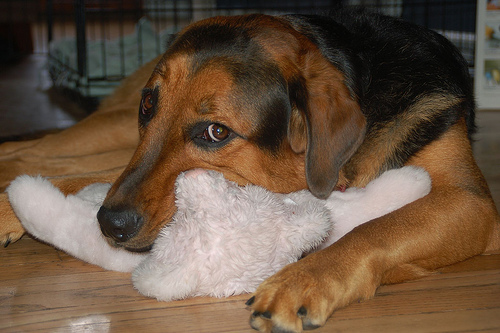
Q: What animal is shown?
A: Dog.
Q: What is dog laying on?
A: Toy.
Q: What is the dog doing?
A: Lying down.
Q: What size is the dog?
A: Large.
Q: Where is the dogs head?
A: On the toy.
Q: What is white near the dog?
A: Stuffed animal.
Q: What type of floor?
A: Wood.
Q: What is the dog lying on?
A: Wood floor.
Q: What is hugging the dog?
A: Stuffed animal.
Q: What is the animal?
A: Dog.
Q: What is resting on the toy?
A: Dog's head.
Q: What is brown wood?
A: Floor.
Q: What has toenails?
A: Dog paws.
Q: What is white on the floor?
A: Dog toy.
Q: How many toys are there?
A: One.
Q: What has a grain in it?
A: Wood floor.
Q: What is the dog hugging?
A: A toy.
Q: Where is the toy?
A: Under the dog.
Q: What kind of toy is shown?
A: A teddy bear.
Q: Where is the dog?
A: On the floor.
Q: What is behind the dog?
A: A cage.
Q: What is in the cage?
A: Blanket.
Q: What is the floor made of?
A: Wood.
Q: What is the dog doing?
A: Looking at the camera.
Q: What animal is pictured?
A: A dog.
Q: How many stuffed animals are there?
A: 1.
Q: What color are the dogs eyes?
A: Brown.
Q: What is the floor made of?
A: Wood.